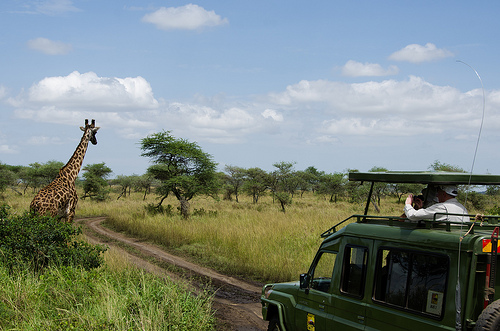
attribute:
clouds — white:
[73, 76, 162, 111]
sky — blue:
[94, 14, 176, 70]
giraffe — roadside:
[14, 107, 127, 240]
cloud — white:
[381, 39, 458, 68]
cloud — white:
[327, 55, 404, 84]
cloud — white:
[130, 2, 240, 38]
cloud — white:
[15, 32, 76, 62]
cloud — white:
[20, 67, 162, 112]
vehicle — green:
[304, 208, 479, 303]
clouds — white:
[394, 40, 456, 70]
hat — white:
[432, 181, 457, 195]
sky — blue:
[0, 2, 499, 188]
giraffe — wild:
[28, 119, 100, 241]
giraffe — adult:
[22, 101, 143, 283]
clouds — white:
[259, 77, 492, 123]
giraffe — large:
[28, 118, 99, 222]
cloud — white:
[144, 3, 234, 30]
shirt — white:
[399, 191, 478, 227]